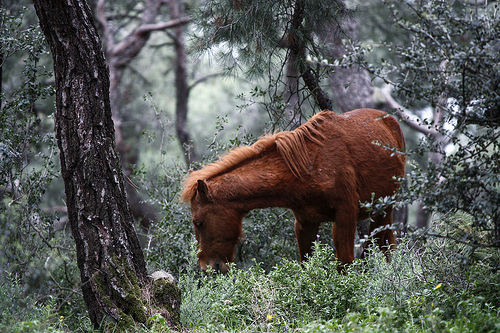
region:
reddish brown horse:
[179, 102, 412, 289]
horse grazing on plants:
[178, 100, 413, 295]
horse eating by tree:
[41, 3, 416, 332]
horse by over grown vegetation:
[180, 102, 497, 327]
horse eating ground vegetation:
[178, 101, 417, 308]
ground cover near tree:
[31, 0, 497, 332]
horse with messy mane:
[181, 100, 413, 280]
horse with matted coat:
[162, 98, 415, 271]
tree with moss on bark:
[37, 17, 182, 331]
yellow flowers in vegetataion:
[250, 276, 450, 326]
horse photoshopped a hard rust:
[166, 98, 421, 288]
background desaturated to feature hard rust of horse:
[0, 0, 497, 332]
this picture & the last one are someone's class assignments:
[1, 0, 498, 332]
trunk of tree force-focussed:
[22, 0, 191, 331]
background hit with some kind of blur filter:
[88, 0, 498, 180]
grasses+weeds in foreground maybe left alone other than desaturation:
[166, 236, 498, 331]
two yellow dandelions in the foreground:
[264, 277, 444, 321]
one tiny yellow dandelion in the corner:
[51, 307, 74, 325]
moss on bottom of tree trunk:
[83, 248, 188, 330]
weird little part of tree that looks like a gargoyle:
[142, 263, 184, 325]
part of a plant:
[343, 257, 375, 279]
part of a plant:
[391, 295, 418, 317]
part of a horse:
[187, 215, 219, 258]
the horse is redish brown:
[170, 90, 435, 285]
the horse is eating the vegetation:
[158, 107, 441, 299]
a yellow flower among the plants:
[431, 282, 446, 292]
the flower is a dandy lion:
[431, 280, 457, 312]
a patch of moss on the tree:
[102, 255, 167, 329]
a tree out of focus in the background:
[168, 91, 206, 164]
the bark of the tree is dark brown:
[87, 147, 108, 207]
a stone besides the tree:
[148, 271, 176, 293]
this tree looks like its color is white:
[380, 90, 455, 244]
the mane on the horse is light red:
[183, 131, 283, 203]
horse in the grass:
[164, 100, 429, 287]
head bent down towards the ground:
[174, 169, 260, 284]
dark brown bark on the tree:
[32, 7, 171, 332]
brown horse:
[171, 111, 423, 271]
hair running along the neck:
[173, 106, 350, 199]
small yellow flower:
[260, 309, 280, 324]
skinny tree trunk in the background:
[160, 36, 217, 176]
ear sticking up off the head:
[189, 178, 214, 205]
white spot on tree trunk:
[94, 182, 108, 209]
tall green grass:
[132, 207, 394, 331]